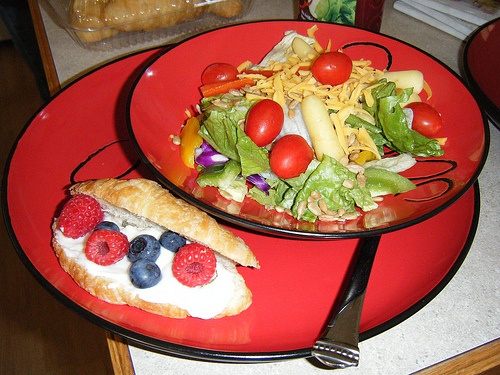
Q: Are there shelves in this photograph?
A: No, there are no shelves.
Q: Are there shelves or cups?
A: No, there are no shelves or cups.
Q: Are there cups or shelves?
A: No, there are no shelves or cups.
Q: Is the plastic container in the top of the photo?
A: Yes, the container is in the top of the image.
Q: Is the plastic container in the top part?
A: Yes, the container is in the top of the image.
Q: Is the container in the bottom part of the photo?
A: No, the container is in the top of the image.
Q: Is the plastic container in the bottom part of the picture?
A: No, the container is in the top of the image.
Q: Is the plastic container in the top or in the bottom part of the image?
A: The container is in the top of the image.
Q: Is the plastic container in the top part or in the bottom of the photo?
A: The container is in the top of the image.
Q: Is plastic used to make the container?
A: Yes, the container is made of plastic.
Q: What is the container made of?
A: The container is made of plastic.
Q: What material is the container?
A: The container is made of plastic.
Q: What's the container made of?
A: The container is made of plastic.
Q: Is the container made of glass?
A: No, the container is made of plastic.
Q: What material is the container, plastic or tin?
A: The container is made of plastic.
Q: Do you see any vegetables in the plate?
A: Yes, there is a vegetable in the plate.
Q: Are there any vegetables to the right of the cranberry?
A: Yes, there is a vegetable to the right of the cranberry.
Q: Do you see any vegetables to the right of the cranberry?
A: Yes, there is a vegetable to the right of the cranberry.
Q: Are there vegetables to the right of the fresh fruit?
A: Yes, there is a vegetable to the right of the cranberry.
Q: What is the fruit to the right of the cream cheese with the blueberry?
A: The fruit is a raspberry.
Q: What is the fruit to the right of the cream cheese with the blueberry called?
A: The fruit is a raspberry.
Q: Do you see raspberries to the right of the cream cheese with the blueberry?
A: Yes, there is a raspberry to the right of the cream cheese.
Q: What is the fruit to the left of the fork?
A: The fruit is a raspberry.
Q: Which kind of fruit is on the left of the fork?
A: The fruit is a raspberry.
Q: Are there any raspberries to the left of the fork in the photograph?
A: Yes, there is a raspberry to the left of the fork.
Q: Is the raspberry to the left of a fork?
A: Yes, the raspberry is to the left of a fork.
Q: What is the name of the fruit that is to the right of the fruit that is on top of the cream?
A: The fruit is a raspberry.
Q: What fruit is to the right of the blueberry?
A: The fruit is a raspberry.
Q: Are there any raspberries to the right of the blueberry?
A: Yes, there is a raspberry to the right of the blueberry.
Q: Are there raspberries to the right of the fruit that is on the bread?
A: Yes, there is a raspberry to the right of the blueberry.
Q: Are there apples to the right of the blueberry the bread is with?
A: No, there is a raspberry to the right of the blueberry.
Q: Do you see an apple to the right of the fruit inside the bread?
A: No, there is a raspberry to the right of the blueberry.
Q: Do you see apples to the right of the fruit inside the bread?
A: No, there is a raspberry to the right of the blueberry.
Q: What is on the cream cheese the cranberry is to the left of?
A: The raspberry is on the cream cheese.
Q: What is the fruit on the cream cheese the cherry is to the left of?
A: The fruit is a raspberry.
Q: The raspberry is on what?
A: The raspberry is on the cream cheese.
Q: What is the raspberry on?
A: The raspberry is on the cream cheese.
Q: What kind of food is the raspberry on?
A: The raspberry is on the cream cheese.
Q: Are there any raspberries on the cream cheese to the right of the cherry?
A: Yes, there is a raspberry on the cream cheese.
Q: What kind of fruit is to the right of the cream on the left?
A: The fruit is a raspberry.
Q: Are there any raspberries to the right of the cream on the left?
A: Yes, there is a raspberry to the right of the cream.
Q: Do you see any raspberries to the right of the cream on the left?
A: Yes, there is a raspberry to the right of the cream.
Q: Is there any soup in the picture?
A: No, there is no soup.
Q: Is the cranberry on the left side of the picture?
A: Yes, the cranberry is on the left of the image.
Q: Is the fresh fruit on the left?
A: Yes, the cranberry is on the left of the image.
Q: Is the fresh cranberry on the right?
A: No, the cranberry is on the left of the image.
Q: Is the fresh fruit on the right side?
A: No, the cranberry is on the left of the image.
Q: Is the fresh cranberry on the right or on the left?
A: The cranberry is on the left of the image.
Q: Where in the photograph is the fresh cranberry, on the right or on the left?
A: The cranberry is on the left of the image.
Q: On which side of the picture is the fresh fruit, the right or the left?
A: The cranberry is on the left of the image.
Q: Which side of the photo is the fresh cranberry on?
A: The cranberry is on the left of the image.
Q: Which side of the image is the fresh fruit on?
A: The cranberry is on the left of the image.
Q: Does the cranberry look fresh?
A: Yes, the cranberry is fresh.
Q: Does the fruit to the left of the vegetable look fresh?
A: Yes, the cranberry is fresh.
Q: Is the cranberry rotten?
A: No, the cranberry is fresh.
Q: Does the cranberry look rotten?
A: No, the cranberry is fresh.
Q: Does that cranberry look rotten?
A: No, the cranberry is fresh.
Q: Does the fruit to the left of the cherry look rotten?
A: No, the cranberry is fresh.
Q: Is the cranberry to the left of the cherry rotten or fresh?
A: The cranberry is fresh.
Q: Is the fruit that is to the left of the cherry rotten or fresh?
A: The cranberry is fresh.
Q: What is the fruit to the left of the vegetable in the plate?
A: The fruit is a cranberry.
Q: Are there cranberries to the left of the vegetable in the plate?
A: Yes, there is a cranberry to the left of the vegetable.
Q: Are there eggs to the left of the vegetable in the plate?
A: No, there is a cranberry to the left of the vegetable.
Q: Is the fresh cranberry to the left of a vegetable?
A: Yes, the cranberry is to the left of a vegetable.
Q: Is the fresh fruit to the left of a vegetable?
A: Yes, the cranberry is to the left of a vegetable.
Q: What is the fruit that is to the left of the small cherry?
A: The fruit is a cranberry.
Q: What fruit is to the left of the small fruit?
A: The fruit is a cranberry.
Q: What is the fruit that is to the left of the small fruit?
A: The fruit is a cranberry.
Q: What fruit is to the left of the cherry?
A: The fruit is a cranberry.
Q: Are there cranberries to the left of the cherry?
A: Yes, there is a cranberry to the left of the cherry.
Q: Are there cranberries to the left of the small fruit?
A: Yes, there is a cranberry to the left of the cherry.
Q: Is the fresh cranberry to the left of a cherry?
A: Yes, the cranberry is to the left of a cherry.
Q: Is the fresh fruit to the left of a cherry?
A: Yes, the cranberry is to the left of a cherry.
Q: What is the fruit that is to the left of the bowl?
A: The fruit is a cranberry.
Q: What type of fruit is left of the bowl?
A: The fruit is a cranberry.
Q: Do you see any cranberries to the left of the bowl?
A: Yes, there is a cranberry to the left of the bowl.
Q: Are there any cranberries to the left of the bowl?
A: Yes, there is a cranberry to the left of the bowl.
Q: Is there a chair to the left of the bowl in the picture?
A: No, there is a cranberry to the left of the bowl.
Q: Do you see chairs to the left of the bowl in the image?
A: No, there is a cranberry to the left of the bowl.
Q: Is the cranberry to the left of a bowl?
A: Yes, the cranberry is to the left of a bowl.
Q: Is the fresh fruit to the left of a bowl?
A: Yes, the cranberry is to the left of a bowl.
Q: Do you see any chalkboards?
A: No, there are no chalkboards.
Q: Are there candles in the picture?
A: No, there are no candles.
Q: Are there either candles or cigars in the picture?
A: No, there are no candles or cigars.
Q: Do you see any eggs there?
A: No, there are no eggs.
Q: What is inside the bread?
A: The blueberry is inside the bread.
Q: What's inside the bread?
A: The blueberry is inside the bread.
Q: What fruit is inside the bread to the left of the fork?
A: The fruit is a blueberry.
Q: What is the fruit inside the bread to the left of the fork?
A: The fruit is a blueberry.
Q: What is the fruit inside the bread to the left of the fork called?
A: The fruit is a blueberry.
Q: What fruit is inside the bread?
A: The fruit is a blueberry.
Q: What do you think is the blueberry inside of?
A: The blueberry is inside the bread.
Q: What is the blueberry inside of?
A: The blueberry is inside the bread.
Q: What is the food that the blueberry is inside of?
A: The food is a bread.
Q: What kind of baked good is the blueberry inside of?
A: The blueberry is inside the bread.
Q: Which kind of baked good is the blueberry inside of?
A: The blueberry is inside the bread.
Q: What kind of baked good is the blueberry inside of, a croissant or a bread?
A: The blueberry is inside a bread.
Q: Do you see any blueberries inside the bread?
A: Yes, there is a blueberry inside the bread.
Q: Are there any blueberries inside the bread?
A: Yes, there is a blueberry inside the bread.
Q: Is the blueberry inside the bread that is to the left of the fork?
A: Yes, the blueberry is inside the bread.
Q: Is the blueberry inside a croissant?
A: No, the blueberry is inside the bread.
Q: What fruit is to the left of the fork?
A: The fruit is a blueberry.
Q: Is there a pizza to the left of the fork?
A: No, there is a blueberry to the left of the fork.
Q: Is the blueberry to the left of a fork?
A: Yes, the blueberry is to the left of a fork.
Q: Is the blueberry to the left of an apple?
A: No, the blueberry is to the left of a fork.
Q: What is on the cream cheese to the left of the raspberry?
A: The blueberry is on the cream cheese.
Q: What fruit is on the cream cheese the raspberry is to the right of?
A: The fruit is a blueberry.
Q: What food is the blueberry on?
A: The blueberry is on the cream cheese.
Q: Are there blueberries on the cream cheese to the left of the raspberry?
A: Yes, there is a blueberry on the cream cheese.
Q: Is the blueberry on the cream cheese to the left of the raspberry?
A: Yes, the blueberry is on the cream cheese.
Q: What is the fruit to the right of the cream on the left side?
A: The fruit is a blueberry.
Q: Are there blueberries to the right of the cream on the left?
A: Yes, there is a blueberry to the right of the cream.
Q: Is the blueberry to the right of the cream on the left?
A: Yes, the blueberry is to the right of the cream.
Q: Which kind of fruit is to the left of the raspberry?
A: The fruit is a blueberry.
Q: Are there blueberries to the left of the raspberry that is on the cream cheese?
A: Yes, there is a blueberry to the left of the raspberry.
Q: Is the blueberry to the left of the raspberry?
A: Yes, the blueberry is to the left of the raspberry.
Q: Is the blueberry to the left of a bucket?
A: No, the blueberry is to the left of the raspberry.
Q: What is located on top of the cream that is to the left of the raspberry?
A: The blueberry is on top of the cream.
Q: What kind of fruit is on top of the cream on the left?
A: The fruit is a blueberry.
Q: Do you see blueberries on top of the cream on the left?
A: Yes, there is a blueberry on top of the cream.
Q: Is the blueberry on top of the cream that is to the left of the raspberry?
A: Yes, the blueberry is on top of the cream.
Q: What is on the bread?
A: The blueberry is on the bread.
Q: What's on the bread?
A: The blueberry is on the bread.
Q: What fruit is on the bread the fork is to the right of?
A: The fruit is a blueberry.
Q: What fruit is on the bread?
A: The fruit is a blueberry.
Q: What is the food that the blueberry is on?
A: The food is a bread.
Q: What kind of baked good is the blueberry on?
A: The blueberry is on the bread.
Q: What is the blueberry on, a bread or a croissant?
A: The blueberry is on a bread.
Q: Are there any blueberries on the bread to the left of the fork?
A: Yes, there is a blueberry on the bread.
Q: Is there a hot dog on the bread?
A: No, there is a blueberry on the bread.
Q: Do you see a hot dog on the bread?
A: No, there is a blueberry on the bread.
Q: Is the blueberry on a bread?
A: Yes, the blueberry is on a bread.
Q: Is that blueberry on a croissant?
A: No, the blueberry is on a bread.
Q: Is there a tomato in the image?
A: Yes, there is a tomato.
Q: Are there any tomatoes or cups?
A: Yes, there is a tomato.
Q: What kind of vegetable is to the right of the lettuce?
A: The vegetable is a tomato.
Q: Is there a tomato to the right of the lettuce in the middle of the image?
A: Yes, there is a tomato to the right of the lettuce.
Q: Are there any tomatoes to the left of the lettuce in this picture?
A: No, the tomato is to the right of the lettuce.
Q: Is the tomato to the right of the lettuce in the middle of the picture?
A: Yes, the tomato is to the right of the lettuce.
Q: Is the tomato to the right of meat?
A: No, the tomato is to the right of the lettuce.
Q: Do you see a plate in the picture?
A: Yes, there is a plate.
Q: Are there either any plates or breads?
A: Yes, there is a plate.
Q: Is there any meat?
A: No, there is no meat.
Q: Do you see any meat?
A: No, there is no meat.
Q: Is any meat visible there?
A: No, there is no meat.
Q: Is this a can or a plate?
A: This is a plate.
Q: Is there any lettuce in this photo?
A: Yes, there is lettuce.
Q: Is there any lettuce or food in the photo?
A: Yes, there is lettuce.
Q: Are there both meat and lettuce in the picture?
A: No, there is lettuce but no meat.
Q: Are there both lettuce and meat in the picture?
A: No, there is lettuce but no meat.